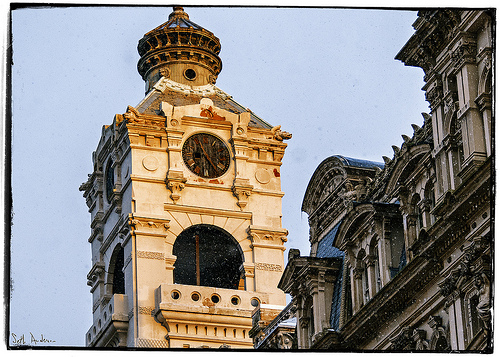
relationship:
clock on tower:
[180, 132, 233, 179] [69, 11, 299, 345]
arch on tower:
[98, 237, 130, 292] [69, 11, 299, 345]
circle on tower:
[140, 155, 158, 172] [69, 11, 299, 345]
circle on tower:
[256, 169, 271, 181] [69, 11, 299, 345]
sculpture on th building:
[461, 277, 496, 327] [258, 11, 491, 341]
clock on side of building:
[182, 134, 226, 182] [76, 7, 294, 348]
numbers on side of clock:
[185, 147, 200, 171] [177, 124, 230, 181]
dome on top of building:
[135, 7, 223, 94] [76, 7, 294, 348]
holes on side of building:
[161, 290, 262, 307] [76, 7, 294, 348]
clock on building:
[180, 132, 233, 179] [76, 7, 294, 348]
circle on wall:
[137, 150, 159, 170] [137, 105, 286, 343]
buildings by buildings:
[256, 13, 494, 346] [88, 11, 290, 343]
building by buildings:
[76, 7, 294, 348] [281, 34, 474, 355]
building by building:
[76, 7, 294, 348] [258, 11, 491, 341]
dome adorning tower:
[135, 7, 223, 95] [69, 11, 299, 345]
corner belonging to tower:
[119, 177, 161, 240] [69, 11, 299, 345]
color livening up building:
[312, 217, 345, 327] [258, 11, 491, 341]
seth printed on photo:
[9, 327, 29, 347] [10, 5, 484, 347]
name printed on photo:
[4, 310, 101, 349] [10, 5, 484, 347]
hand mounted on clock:
[201, 150, 227, 174] [184, 123, 252, 178]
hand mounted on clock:
[196, 136, 206, 153] [168, 110, 258, 198]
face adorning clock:
[182, 130, 229, 178] [186, 130, 236, 174]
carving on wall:
[163, 164, 188, 203] [131, 112, 286, 354]